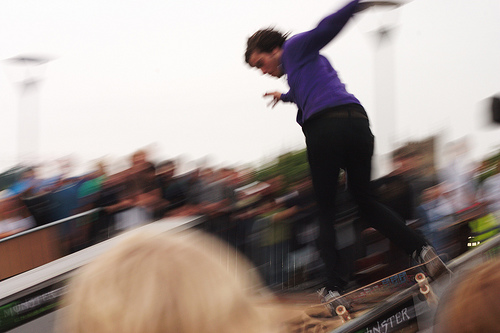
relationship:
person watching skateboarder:
[103, 150, 160, 210] [241, 1, 431, 297]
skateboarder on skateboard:
[241, 1, 431, 297] [307, 252, 449, 312]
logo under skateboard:
[357, 306, 411, 332] [307, 252, 449, 312]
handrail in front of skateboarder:
[1, 214, 206, 307] [241, 1, 431, 297]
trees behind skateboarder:
[254, 149, 308, 182] [241, 1, 431, 297]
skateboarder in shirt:
[241, 1, 431, 297] [274, 0, 359, 119]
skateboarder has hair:
[241, 1, 431, 297] [245, 28, 288, 60]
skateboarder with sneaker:
[241, 1, 431, 297] [315, 286, 350, 316]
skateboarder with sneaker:
[241, 1, 431, 297] [414, 243, 452, 283]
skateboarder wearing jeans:
[241, 1, 431, 297] [301, 109, 424, 291]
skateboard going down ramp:
[307, 252, 449, 312] [325, 233, 497, 331]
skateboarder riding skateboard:
[241, 1, 431, 297] [307, 252, 449, 312]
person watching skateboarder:
[9, 165, 61, 191] [241, 1, 431, 297]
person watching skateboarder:
[195, 165, 242, 186] [241, 1, 431, 297]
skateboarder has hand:
[241, 1, 431, 297] [261, 87, 281, 108]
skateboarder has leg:
[241, 1, 431, 297] [345, 158, 428, 255]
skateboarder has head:
[241, 1, 431, 297] [243, 24, 285, 77]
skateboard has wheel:
[307, 252, 449, 312] [419, 284, 430, 295]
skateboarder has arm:
[241, 1, 431, 297] [294, 1, 382, 52]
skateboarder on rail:
[241, 1, 431, 297] [325, 233, 497, 331]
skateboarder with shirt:
[241, 1, 431, 297] [274, 0, 359, 119]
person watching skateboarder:
[155, 159, 181, 179] [241, 1, 431, 297]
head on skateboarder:
[436, 258, 499, 332] [241, 1, 431, 297]